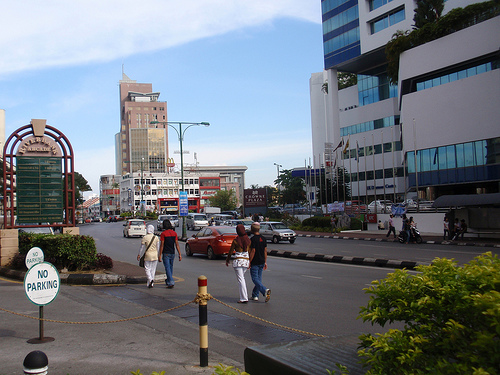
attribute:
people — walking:
[228, 216, 277, 304]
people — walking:
[138, 215, 182, 290]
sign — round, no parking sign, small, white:
[21, 258, 63, 349]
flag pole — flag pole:
[368, 134, 379, 215]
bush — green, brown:
[22, 229, 102, 270]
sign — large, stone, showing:
[4, 114, 79, 228]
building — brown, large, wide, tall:
[108, 77, 175, 226]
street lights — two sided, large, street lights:
[148, 117, 217, 239]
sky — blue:
[6, 1, 320, 144]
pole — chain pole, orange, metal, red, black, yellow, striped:
[195, 269, 217, 365]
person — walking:
[158, 215, 186, 289]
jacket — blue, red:
[159, 229, 177, 254]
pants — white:
[230, 263, 255, 302]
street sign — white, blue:
[173, 190, 191, 217]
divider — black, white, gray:
[258, 239, 471, 284]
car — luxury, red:
[181, 222, 242, 260]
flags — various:
[304, 137, 445, 176]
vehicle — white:
[121, 216, 148, 241]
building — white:
[306, 1, 499, 240]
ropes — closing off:
[3, 289, 336, 334]